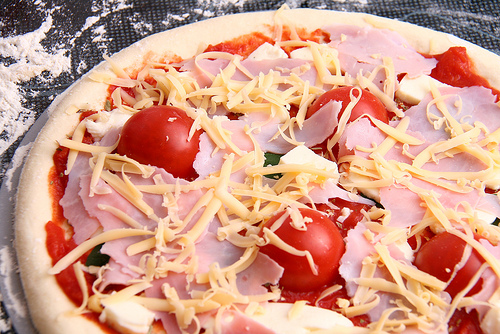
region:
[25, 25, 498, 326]
an uncooked pizza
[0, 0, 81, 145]
white flour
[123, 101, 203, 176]
a cherry tomato on a pizza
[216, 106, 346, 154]
bits of ham on a pizza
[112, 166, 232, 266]
orange shredded cheese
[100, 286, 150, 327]
square of white cheese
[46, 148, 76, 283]
tomato sauce on a pizza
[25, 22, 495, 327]
a pizza with ham and cheese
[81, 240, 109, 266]
a bit of sliced green onion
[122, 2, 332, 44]
uncooked dough of a pizza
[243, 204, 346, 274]
The tomato is red.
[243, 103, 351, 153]
The ham is on the pizza.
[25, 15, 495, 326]
The cheese is on the pizza.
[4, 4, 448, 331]
The pizza is not cooked.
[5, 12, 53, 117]
The flour is on the table.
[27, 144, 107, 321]
The sauce is on the pizza.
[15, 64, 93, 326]
The pizza dough is tan.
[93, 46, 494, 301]
The tomatoes are spread on the pizza.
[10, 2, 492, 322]
The pizza is on the tray.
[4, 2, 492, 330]
The pizza has many toppings.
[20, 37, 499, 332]
this is the pizza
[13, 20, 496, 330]
the pizza is round in shape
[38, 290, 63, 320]
the edge is brown in color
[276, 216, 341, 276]
this is a tomato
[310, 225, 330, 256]
the tomato is red in color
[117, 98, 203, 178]
the tomato is round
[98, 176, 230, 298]
these are some cheese strips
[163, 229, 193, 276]
the strips are yellow in color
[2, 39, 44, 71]
these are some particles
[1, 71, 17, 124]
the particles are white in color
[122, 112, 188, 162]
this is a tomato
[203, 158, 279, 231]
this is spaghetti on the plate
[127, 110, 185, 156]
the tomato is ripe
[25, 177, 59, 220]
this is a pizza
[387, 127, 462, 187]
the spaghetti is yellow in color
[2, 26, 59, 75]
the floor has poured in the floor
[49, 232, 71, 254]
the spice is red in color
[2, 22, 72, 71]
the floor is white in color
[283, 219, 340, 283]
the tomato is whole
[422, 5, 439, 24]
the mat is black in color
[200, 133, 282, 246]
the shredded cheese is orange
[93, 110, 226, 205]
cherry tomato on pizza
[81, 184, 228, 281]
pieces of ham on the pizza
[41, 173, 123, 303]
the sauce is on the dough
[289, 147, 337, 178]
the cheese is white chunks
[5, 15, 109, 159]
flour is on the table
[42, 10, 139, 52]
table top is black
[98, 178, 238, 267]
the shredded cheese is on the ham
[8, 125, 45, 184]
pizza on a sheet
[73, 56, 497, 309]
the pizza is uncooked